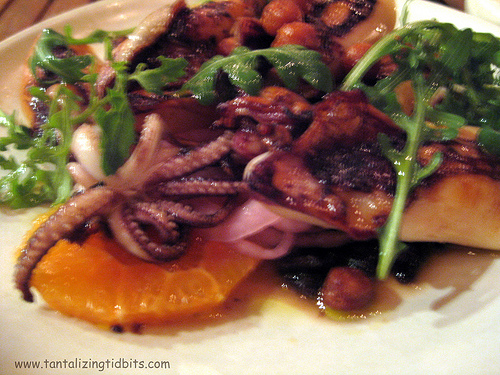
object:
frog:
[407, 250, 489, 310]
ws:
[11, 360, 40, 368]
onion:
[188, 196, 311, 261]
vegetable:
[0, 22, 188, 209]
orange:
[30, 233, 260, 331]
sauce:
[416, 250, 496, 311]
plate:
[1, 1, 499, 373]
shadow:
[412, 244, 499, 311]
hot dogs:
[28, 231, 260, 327]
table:
[0, 0, 133, 71]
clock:
[0, 0, 500, 375]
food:
[0, 0, 500, 334]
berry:
[323, 267, 373, 312]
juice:
[258, 268, 472, 323]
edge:
[0, 3, 98, 52]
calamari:
[12, 112, 251, 302]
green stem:
[339, 4, 500, 282]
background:
[0, 252, 500, 375]